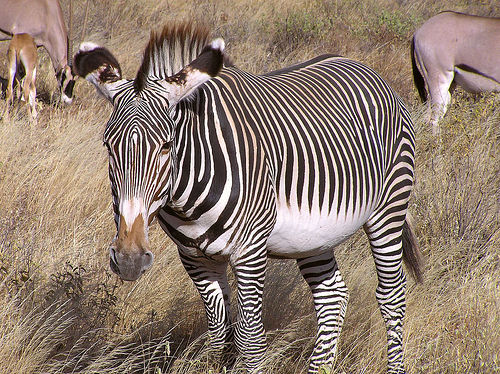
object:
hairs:
[130, 17, 244, 84]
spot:
[116, 207, 146, 249]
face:
[99, 81, 180, 282]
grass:
[8, 146, 67, 328]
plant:
[272, 10, 342, 50]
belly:
[254, 193, 368, 262]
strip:
[368, 226, 409, 243]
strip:
[373, 254, 405, 269]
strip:
[371, 221, 404, 240]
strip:
[369, 210, 409, 224]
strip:
[383, 180, 406, 204]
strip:
[298, 256, 335, 270]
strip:
[300, 265, 343, 284]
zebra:
[64, 10, 444, 370]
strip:
[317, 306, 343, 316]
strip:
[188, 270, 218, 282]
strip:
[233, 261, 267, 281]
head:
[69, 33, 227, 283]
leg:
[230, 253, 270, 364]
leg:
[376, 213, 406, 367]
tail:
[393, 205, 427, 294]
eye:
[156, 137, 173, 157]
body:
[194, 52, 395, 258]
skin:
[265, 71, 400, 171]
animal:
[0, 30, 48, 130]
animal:
[409, 6, 497, 127]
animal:
[63, 21, 426, 365]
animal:
[0, 0, 76, 117]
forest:
[0, 0, 500, 368]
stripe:
[319, 76, 365, 144]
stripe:
[305, 95, 337, 142]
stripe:
[295, 109, 325, 163]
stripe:
[284, 110, 322, 186]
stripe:
[294, 101, 335, 176]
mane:
[132, 19, 227, 86]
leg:
[230, 245, 268, 360]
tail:
[399, 213, 431, 292]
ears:
[74, 39, 136, 95]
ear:
[156, 34, 228, 94]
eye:
[159, 142, 175, 154]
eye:
[101, 140, 115, 156]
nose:
[110, 247, 150, 279]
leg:
[179, 252, 229, 368]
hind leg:
[364, 197, 411, 374]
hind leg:
[296, 246, 349, 374]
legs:
[183, 220, 413, 367]